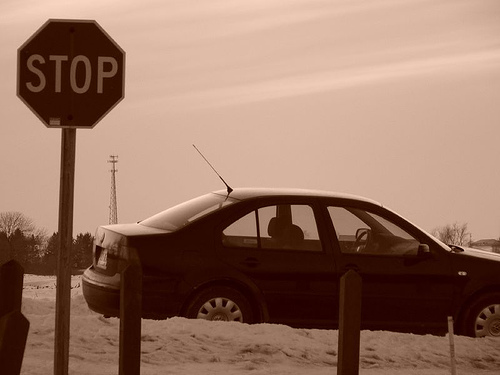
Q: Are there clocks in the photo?
A: No, there are no clocks.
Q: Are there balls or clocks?
A: No, there are no clocks or balls.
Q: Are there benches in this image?
A: No, there are no benches.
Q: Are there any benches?
A: No, there are no benches.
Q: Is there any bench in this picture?
A: No, there are no benches.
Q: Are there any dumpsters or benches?
A: No, there are no benches or dumpsters.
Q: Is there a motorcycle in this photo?
A: No, there are no motorcycles.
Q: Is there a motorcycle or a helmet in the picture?
A: No, there are no motorcycles or helmets.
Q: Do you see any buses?
A: No, there are no buses.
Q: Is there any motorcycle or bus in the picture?
A: No, there are no buses or motorcycles.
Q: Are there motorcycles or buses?
A: No, there are no buses or motorcycles.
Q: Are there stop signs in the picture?
A: Yes, there is a stop sign.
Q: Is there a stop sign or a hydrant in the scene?
A: Yes, there is a stop sign.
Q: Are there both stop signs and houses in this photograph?
A: No, there is a stop sign but no houses.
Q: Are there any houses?
A: No, there are no houses.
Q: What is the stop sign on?
A: The stop sign is on the pole.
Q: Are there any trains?
A: No, there are no trains.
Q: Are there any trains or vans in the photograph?
A: No, there are no trains or vans.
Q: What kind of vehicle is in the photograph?
A: The vehicle is a car.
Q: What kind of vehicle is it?
A: The vehicle is a car.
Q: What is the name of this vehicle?
A: This is a car.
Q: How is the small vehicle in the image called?
A: The vehicle is a car.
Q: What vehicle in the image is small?
A: The vehicle is a car.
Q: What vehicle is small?
A: The vehicle is a car.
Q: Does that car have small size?
A: Yes, the car is small.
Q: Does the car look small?
A: Yes, the car is small.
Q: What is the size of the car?
A: The car is small.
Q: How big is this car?
A: The car is small.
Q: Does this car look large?
A: No, the car is small.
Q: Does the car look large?
A: No, the car is small.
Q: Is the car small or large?
A: The car is small.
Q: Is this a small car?
A: Yes, this is a small car.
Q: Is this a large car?
A: No, this is a small car.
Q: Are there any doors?
A: Yes, there is a door.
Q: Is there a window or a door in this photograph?
A: Yes, there is a door.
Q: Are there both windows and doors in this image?
A: Yes, there are both a door and windows.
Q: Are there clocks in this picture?
A: No, there are no clocks.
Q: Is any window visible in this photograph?
A: Yes, there is a window.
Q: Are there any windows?
A: Yes, there is a window.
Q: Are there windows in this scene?
A: Yes, there is a window.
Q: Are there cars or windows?
A: Yes, there is a window.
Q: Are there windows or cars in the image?
A: Yes, there is a window.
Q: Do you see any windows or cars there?
A: Yes, there is a window.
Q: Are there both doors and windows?
A: Yes, there are both a window and a door.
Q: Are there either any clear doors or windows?
A: Yes, there is a clear window.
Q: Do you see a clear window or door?
A: Yes, there is a clear window.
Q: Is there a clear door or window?
A: Yes, there is a clear window.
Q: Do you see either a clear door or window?
A: Yes, there is a clear window.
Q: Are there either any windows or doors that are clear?
A: Yes, the window is clear.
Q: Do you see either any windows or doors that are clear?
A: Yes, the window is clear.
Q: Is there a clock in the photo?
A: No, there are no clocks.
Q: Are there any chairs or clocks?
A: No, there are no clocks or chairs.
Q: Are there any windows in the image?
A: Yes, there is a window.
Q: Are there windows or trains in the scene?
A: Yes, there is a window.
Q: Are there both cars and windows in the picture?
A: Yes, there are both a window and a car.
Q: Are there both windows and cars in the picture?
A: Yes, there are both a window and a car.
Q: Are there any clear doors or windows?
A: Yes, there is a clear window.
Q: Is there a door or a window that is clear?
A: Yes, the window is clear.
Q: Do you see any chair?
A: No, there are no chairs.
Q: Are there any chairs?
A: No, there are no chairs.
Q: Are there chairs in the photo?
A: No, there are no chairs.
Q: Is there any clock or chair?
A: No, there are no chairs or clocks.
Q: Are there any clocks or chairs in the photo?
A: No, there are no chairs or clocks.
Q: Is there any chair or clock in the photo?
A: No, there are no chairs or clocks.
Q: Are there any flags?
A: No, there are no flags.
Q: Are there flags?
A: No, there are no flags.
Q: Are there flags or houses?
A: No, there are no flags or houses.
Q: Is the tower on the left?
A: Yes, the tower is on the left of the image.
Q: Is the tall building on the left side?
A: Yes, the tower is on the left of the image.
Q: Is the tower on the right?
A: No, the tower is on the left of the image.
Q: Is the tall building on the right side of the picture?
A: No, the tower is on the left of the image.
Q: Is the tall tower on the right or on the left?
A: The tower is on the left of the image.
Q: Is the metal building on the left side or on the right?
A: The tower is on the left of the image.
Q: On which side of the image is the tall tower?
A: The tower is on the left of the image.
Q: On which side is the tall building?
A: The tower is on the left of the image.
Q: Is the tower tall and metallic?
A: Yes, the tower is tall and metallic.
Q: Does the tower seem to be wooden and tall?
A: No, the tower is tall but metallic.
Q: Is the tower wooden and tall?
A: No, the tower is tall but metallic.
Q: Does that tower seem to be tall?
A: Yes, the tower is tall.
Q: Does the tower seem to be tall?
A: Yes, the tower is tall.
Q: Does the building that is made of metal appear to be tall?
A: Yes, the tower is tall.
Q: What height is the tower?
A: The tower is tall.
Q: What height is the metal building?
A: The tower is tall.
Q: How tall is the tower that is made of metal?
A: The tower is tall.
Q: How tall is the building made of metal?
A: The tower is tall.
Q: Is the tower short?
A: No, the tower is tall.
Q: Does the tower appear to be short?
A: No, the tower is tall.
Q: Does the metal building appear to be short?
A: No, the tower is tall.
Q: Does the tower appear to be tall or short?
A: The tower is tall.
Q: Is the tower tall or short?
A: The tower is tall.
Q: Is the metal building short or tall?
A: The tower is tall.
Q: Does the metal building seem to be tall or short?
A: The tower is tall.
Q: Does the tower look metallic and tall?
A: Yes, the tower is metallic and tall.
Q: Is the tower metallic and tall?
A: Yes, the tower is metallic and tall.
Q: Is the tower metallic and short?
A: No, the tower is metallic but tall.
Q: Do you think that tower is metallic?
A: Yes, the tower is metallic.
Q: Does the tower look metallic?
A: Yes, the tower is metallic.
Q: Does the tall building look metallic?
A: Yes, the tower is metallic.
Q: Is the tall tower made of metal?
A: Yes, the tower is made of metal.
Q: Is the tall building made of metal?
A: Yes, the tower is made of metal.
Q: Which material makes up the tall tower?
A: The tower is made of metal.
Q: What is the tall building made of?
A: The tower is made of metal.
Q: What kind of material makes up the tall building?
A: The tower is made of metal.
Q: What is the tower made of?
A: The tower is made of metal.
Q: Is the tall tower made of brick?
A: No, the tower is made of metal.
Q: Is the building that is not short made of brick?
A: No, the tower is made of metal.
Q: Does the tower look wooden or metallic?
A: The tower is metallic.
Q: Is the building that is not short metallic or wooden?
A: The tower is metallic.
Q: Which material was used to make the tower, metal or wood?
A: The tower is made of metal.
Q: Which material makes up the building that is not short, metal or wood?
A: The tower is made of metal.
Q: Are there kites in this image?
A: No, there are no kites.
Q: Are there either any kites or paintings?
A: No, there are no kites or paintings.